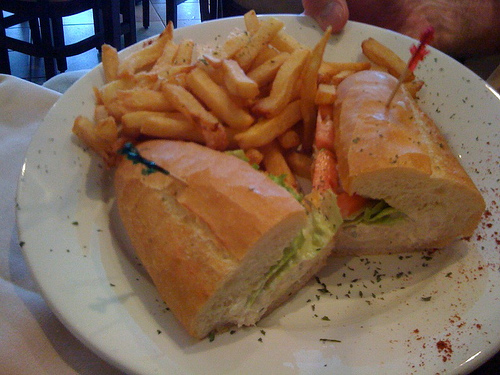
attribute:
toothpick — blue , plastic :
[123, 142, 193, 188]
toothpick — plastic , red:
[384, 22, 444, 120]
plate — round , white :
[27, 19, 490, 369]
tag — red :
[404, 22, 428, 70]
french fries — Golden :
[95, 9, 375, 153]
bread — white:
[112, 145, 299, 375]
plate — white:
[107, 292, 487, 375]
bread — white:
[155, 225, 253, 325]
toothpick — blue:
[122, 162, 172, 180]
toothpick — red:
[392, 99, 418, 146]